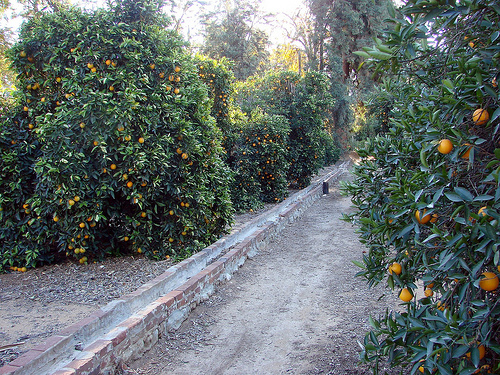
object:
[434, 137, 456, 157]
orange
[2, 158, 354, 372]
brick slab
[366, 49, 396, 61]
leaf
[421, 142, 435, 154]
leaf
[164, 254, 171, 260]
orange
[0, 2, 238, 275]
large bushes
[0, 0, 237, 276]
lemon trees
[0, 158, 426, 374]
brown leaves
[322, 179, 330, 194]
small brown structur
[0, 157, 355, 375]
crevice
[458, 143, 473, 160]
yellow lemons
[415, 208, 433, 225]
orange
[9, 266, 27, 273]
four oranges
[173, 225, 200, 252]
leaves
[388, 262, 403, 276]
orange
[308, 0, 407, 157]
tall trees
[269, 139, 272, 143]
orange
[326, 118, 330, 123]
orange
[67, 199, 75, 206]
orange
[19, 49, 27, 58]
orange